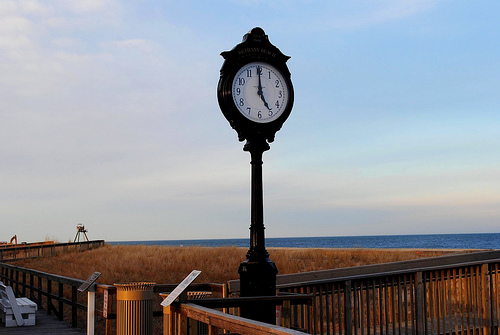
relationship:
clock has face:
[218, 24, 301, 329] [231, 60, 289, 123]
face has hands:
[231, 60, 289, 123] [254, 67, 273, 115]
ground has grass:
[2, 232, 497, 333] [29, 241, 470, 277]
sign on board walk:
[162, 264, 202, 308] [2, 238, 497, 334]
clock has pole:
[218, 24, 301, 329] [239, 140, 281, 324]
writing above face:
[236, 46, 284, 58] [231, 60, 289, 123]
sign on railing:
[162, 264, 202, 308] [167, 291, 321, 334]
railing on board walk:
[167, 291, 321, 334] [2, 238, 497, 334]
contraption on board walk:
[72, 222, 92, 244] [2, 238, 497, 334]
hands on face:
[254, 67, 273, 115] [231, 60, 289, 123]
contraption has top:
[72, 222, 92, 244] [72, 222, 89, 234]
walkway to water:
[151, 245, 500, 332] [108, 234, 499, 250]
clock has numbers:
[218, 24, 301, 329] [234, 68, 284, 122]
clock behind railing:
[218, 24, 301, 329] [167, 291, 321, 334]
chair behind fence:
[1, 282, 38, 329] [3, 244, 499, 335]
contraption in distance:
[72, 222, 92, 244] [1, 155, 491, 264]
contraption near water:
[72, 222, 92, 244] [108, 234, 499, 250]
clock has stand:
[218, 24, 301, 329] [233, 256, 279, 325]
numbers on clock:
[234, 68, 284, 122] [218, 24, 301, 329]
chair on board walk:
[1, 282, 38, 329] [2, 238, 497, 334]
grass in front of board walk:
[29, 241, 470, 277] [2, 238, 497, 334]